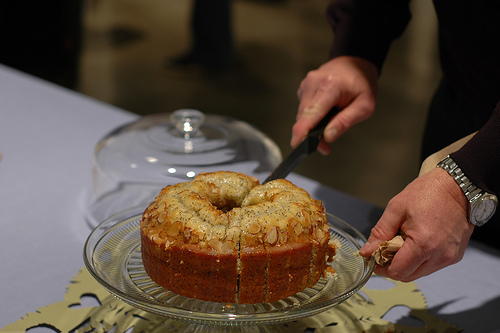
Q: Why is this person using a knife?
A: To cut cake.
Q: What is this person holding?
A: A knife.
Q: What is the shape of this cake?
A: Round.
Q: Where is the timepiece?
A: On the wrist.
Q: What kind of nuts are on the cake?
A: Almonds.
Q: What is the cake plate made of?
A: Glass.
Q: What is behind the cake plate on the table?
A: The cake lid.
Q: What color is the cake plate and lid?
A: Clear glass.